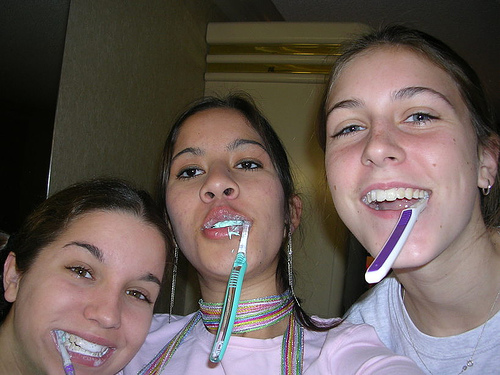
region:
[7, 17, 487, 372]
Three women brushing their teeth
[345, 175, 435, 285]
A toothbrush in a mouth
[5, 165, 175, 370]
A woman smiling with a toothbrush in her mouth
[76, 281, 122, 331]
A woman's nose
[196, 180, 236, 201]
The nostrils of a nose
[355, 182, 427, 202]
A row of top teeth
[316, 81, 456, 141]
A smiling woman's eyes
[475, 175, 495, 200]
An earring in an earlobe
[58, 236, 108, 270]
A woman's right eyebrow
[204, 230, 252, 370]
The handle of a toothbrush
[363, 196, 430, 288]
white and purple toothbrush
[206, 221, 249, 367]
light blue and clear toothbrush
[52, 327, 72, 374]
white and purple toothbrush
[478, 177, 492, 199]
silver earing in the woman's left ear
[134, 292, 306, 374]
rainbow color scarf around the woman's neck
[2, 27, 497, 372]
three girls brushing their teeth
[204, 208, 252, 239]
toothpaste hanging out of the girl's mouth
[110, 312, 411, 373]
the girl is wearing a light pink shirt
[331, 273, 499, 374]
the girl is wearing a light gray shirt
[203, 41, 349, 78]
gold bands on the back wall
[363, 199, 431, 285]
purple and white toothbrush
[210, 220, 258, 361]
mint and white toothbrush being used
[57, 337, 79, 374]
purple and white toothbrush being used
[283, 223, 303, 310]
long earring hanging from ear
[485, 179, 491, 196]
small hoop earring hanging from ear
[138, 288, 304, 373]
decorative scarf wrapped around neck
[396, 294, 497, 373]
necklace chain hanging from neck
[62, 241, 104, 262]
eyebrow on girl's face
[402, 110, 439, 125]
eye on girl's face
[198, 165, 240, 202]
nose on girl's face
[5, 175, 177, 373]
A brown haired girl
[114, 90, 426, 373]
A girl with dark hair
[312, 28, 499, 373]
A girl with a pony tail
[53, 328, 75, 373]
A purple and white toothbrush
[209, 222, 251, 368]
A teal and white toothbrush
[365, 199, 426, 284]
A toothbrush handle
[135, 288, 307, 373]
A thin scarf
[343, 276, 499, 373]
A grey shirt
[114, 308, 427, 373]
A pink shirt with sleeves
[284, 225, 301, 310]
A dangling earing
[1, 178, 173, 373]
girl to the left of girl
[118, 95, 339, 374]
girl to the right of girl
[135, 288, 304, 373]
girl wearing a colorful scarf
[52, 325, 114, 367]
mouth is open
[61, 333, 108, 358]
white teeth inside mouth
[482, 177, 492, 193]
silver hoop earrings hanging from ear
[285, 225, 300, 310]
long dangly earring hanging from ear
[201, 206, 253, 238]
thick pouty lips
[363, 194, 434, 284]
toothbrush inside mouth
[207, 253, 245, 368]
toothbrush handle is blue